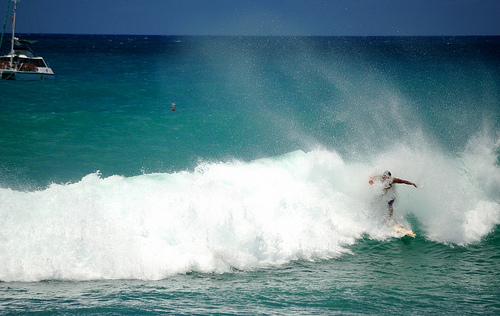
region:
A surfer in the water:
[359, 147, 433, 263]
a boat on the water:
[8, 1, 88, 85]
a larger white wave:
[20, 148, 356, 281]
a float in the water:
[164, 91, 186, 116]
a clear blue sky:
[34, 4, 496, 44]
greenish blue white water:
[46, 48, 183, 204]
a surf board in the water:
[380, 214, 435, 252]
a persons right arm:
[393, 172, 422, 199]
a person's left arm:
[359, 168, 386, 193]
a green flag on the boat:
[0, 24, 50, 57]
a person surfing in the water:
[214, 80, 473, 310]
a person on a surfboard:
[304, 132, 491, 307]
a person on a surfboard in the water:
[239, 143, 468, 302]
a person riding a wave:
[164, 69, 454, 310]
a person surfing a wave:
[226, 145, 487, 312]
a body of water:
[59, 11, 498, 308]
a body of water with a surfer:
[69, 18, 486, 279]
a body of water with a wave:
[107, 53, 446, 314]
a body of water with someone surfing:
[124, 43, 490, 283]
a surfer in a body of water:
[194, 108, 487, 314]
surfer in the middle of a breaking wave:
[353, 155, 426, 251]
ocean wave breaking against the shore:
[3, 157, 480, 288]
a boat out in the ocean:
[0, 18, 85, 85]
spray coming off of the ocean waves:
[205, 17, 416, 148]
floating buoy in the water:
[151, 88, 189, 119]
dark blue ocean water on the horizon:
[67, 30, 128, 57]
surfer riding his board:
[355, 158, 420, 246]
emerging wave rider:
[333, 161, 428, 246]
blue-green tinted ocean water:
[34, 109, 137, 161]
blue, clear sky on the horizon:
[372, 5, 479, 36]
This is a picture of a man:
[310, 133, 486, 291]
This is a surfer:
[338, 97, 443, 312]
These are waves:
[84, 185, 439, 315]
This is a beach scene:
[41, 41, 451, 313]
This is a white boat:
[3, 32, 60, 84]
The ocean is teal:
[61, 93, 291, 276]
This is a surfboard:
[360, 230, 430, 244]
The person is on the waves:
[328, 110, 480, 282]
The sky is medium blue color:
[115, 16, 286, 91]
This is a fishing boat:
[7, 48, 69, 90]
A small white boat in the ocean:
[3, 5, 73, 94]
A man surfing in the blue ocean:
[329, 120, 454, 275]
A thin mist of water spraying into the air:
[215, 22, 435, 173]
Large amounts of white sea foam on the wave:
[7, 165, 340, 283]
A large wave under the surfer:
[219, 150, 499, 292]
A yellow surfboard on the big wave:
[370, 215, 419, 242]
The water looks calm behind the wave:
[39, 80, 164, 150]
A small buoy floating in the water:
[164, 93, 188, 117]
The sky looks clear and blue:
[218, 7, 420, 33]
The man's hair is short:
[381, 167, 395, 176]